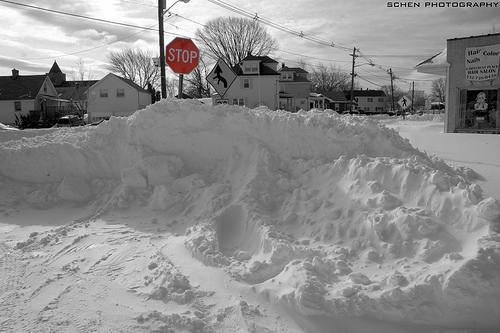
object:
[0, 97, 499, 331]
snow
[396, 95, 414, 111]
sign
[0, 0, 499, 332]
cityscape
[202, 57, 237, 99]
sign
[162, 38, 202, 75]
sign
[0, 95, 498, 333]
snow bank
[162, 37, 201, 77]
stop sign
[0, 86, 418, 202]
mound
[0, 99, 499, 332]
heap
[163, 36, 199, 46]
top